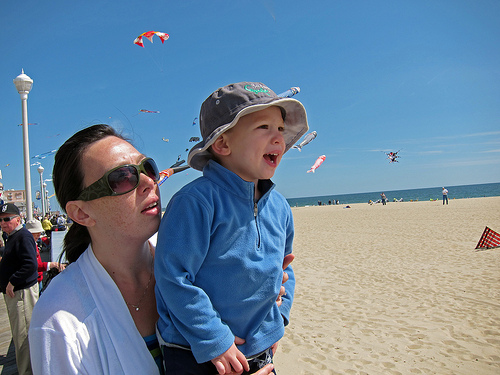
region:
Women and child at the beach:
[27, 79, 311, 374]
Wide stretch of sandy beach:
[287, 196, 498, 373]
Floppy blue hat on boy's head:
[187, 80, 311, 178]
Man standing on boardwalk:
[0, 198, 37, 365]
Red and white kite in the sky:
[132, 24, 169, 55]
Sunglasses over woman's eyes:
[75, 156, 161, 200]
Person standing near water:
[437, 184, 451, 210]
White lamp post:
[12, 69, 33, 236]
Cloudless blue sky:
[0, 2, 497, 197]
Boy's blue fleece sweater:
[154, 166, 296, 358]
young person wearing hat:
[181, 58, 302, 156]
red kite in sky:
[128, 9, 186, 66]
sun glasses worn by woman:
[107, 156, 154, 206]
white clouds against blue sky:
[24, 8, 105, 62]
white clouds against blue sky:
[60, 56, 121, 96]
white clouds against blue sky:
[214, 18, 288, 75]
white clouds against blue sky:
[301, 11, 373, 63]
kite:
[301, 146, 329, 186]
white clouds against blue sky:
[342, 13, 444, 78]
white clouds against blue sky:
[362, 76, 469, 136]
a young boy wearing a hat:
[155, 81, 309, 373]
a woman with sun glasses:
[26, 124, 163, 374]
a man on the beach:
[440, 184, 449, 204]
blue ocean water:
[286, 180, 498, 205]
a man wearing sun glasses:
[0, 202, 42, 373]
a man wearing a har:
[1, 201, 41, 373]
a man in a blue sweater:
[0, 200, 42, 373]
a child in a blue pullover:
[153, 79, 309, 374]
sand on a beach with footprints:
[274, 193, 495, 369]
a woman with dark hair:
[27, 124, 166, 374]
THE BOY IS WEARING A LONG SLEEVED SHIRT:
[138, 157, 307, 367]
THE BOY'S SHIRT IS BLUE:
[151, 156, 301, 359]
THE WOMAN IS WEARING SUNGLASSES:
[63, 153, 163, 210]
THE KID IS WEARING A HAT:
[182, 75, 311, 179]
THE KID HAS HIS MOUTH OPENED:
[258, 144, 287, 177]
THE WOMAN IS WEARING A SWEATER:
[18, 228, 172, 374]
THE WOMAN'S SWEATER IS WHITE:
[18, 229, 180, 374]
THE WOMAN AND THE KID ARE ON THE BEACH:
[24, 76, 317, 373]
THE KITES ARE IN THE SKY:
[133, 78, 418, 192]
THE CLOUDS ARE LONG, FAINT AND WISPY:
[364, 128, 498, 168]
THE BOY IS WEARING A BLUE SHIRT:
[141, 162, 303, 357]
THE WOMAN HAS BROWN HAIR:
[43, 121, 124, 267]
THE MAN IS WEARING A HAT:
[181, 78, 316, 170]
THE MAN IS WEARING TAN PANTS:
[0, 278, 47, 374]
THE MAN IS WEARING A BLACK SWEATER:
[0, 225, 47, 302]